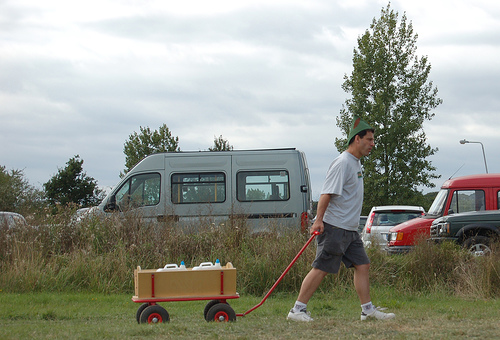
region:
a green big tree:
[337, 22, 429, 221]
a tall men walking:
[286, 109, 378, 332]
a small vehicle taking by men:
[111, 254, 261, 329]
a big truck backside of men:
[97, 143, 327, 245]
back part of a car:
[358, 201, 436, 270]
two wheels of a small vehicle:
[139, 307, 236, 328]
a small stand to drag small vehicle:
[244, 223, 350, 331]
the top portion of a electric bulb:
[451, 134, 496, 174]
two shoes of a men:
[288, 301, 420, 326]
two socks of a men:
[288, 296, 380, 308]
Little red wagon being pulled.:
[124, 229, 314, 329]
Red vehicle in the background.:
[387, 164, 494, 264]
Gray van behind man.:
[73, 143, 315, 238]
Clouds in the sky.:
[3, 5, 498, 232]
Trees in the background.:
[1, 0, 453, 220]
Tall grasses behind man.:
[1, 201, 496, 305]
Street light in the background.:
[452, 135, 498, 178]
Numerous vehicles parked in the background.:
[1, 201, 497, 263]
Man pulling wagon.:
[285, 115, 405, 327]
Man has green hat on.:
[346, 110, 381, 157]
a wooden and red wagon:
[131, 257, 241, 328]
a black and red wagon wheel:
[139, 306, 171, 328]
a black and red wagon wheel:
[203, 303, 234, 323]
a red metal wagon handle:
[232, 224, 318, 318]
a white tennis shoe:
[287, 303, 315, 326]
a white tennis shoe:
[357, 306, 393, 323]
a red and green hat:
[347, 116, 370, 138]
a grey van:
[71, 146, 312, 237]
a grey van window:
[110, 168, 160, 209]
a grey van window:
[172, 171, 223, 202]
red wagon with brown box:
[117, 257, 257, 327]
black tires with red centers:
[124, 297, 244, 332]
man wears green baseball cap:
[343, 116, 382, 170]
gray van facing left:
[61, 147, 317, 242]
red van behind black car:
[387, 172, 497, 262]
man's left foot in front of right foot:
[283, 296, 401, 330]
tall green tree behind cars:
[331, 2, 441, 236]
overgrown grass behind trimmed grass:
[0, 218, 498, 295]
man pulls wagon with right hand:
[256, 220, 336, 320]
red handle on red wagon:
[239, 219, 329, 329]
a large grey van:
[65, 115, 340, 290]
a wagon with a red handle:
[112, 217, 353, 329]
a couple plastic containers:
[151, 251, 223, 278]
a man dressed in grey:
[281, 111, 423, 331]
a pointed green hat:
[331, 106, 386, 147]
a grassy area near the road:
[0, 185, 485, 330]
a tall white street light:
[452, 123, 495, 190]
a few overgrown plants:
[6, 188, 133, 311]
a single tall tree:
[329, 4, 444, 244]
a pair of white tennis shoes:
[280, 297, 404, 324]